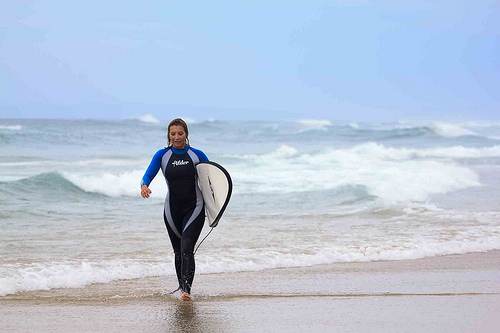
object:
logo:
[207, 176, 216, 201]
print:
[172, 160, 189, 167]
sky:
[0, 0, 499, 129]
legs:
[164, 209, 185, 291]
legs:
[181, 210, 206, 293]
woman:
[140, 117, 209, 301]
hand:
[139, 185, 151, 199]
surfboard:
[196, 161, 233, 227]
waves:
[3, 135, 142, 248]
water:
[10, 138, 159, 203]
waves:
[219, 108, 476, 213]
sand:
[281, 277, 439, 328]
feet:
[179, 292, 191, 301]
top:
[139, 144, 209, 294]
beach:
[1, 248, 498, 332]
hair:
[164, 118, 190, 149]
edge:
[223, 172, 232, 197]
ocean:
[0, 112, 500, 301]